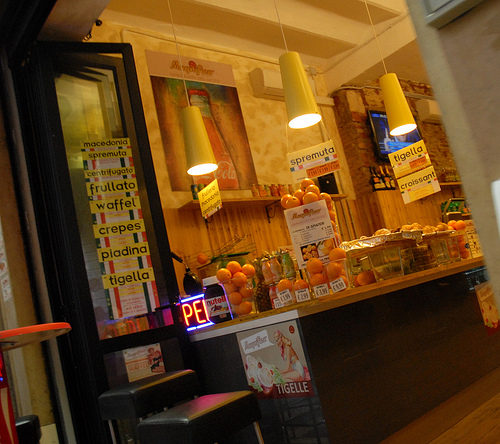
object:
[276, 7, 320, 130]
lights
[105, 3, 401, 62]
ceiling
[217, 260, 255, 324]
oranges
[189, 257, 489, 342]
counter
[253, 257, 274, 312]
pineapple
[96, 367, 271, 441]
two stools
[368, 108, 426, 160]
tv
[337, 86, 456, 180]
building wall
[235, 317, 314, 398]
advertisement sign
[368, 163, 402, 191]
liquor bottles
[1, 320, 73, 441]
table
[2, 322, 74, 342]
red edge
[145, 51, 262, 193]
picture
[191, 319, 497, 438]
wood base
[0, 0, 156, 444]
left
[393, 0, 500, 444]
right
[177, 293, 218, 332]
light up neon sign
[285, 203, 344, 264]
poster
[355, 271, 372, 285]
an orange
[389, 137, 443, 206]
sign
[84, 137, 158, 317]
sticker words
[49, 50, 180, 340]
glass plain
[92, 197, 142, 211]
black and yellow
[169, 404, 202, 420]
leather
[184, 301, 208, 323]
letters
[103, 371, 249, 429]
seats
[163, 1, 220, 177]
long modern light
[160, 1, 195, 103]
cable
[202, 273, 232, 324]
jar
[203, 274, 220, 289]
lid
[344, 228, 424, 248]
tray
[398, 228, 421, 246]
tin foil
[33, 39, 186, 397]
door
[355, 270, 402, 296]
part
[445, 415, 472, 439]
section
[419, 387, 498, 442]
floor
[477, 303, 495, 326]
part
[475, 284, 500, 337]
banner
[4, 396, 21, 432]
an edge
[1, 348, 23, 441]
post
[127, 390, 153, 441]
edge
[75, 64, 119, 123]
part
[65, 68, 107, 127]
glass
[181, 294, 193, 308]
part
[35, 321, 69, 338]
edge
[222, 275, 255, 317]
glass pitcher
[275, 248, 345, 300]
sereral oranges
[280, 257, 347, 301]
glasses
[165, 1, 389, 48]
are suspended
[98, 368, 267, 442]
dark cushions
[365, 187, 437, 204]
shelf